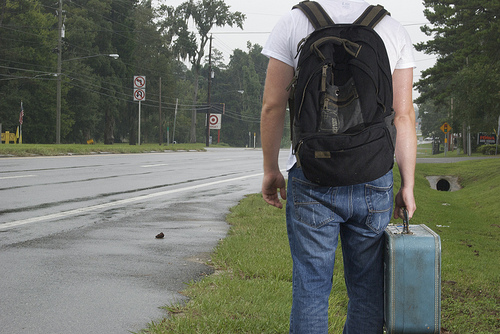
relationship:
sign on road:
[201, 107, 232, 146] [9, 131, 297, 309]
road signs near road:
[129, 73, 154, 150] [9, 131, 297, 309]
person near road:
[229, 0, 470, 333] [9, 131, 297, 309]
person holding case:
[229, 0, 470, 333] [372, 188, 448, 332]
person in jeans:
[229, 0, 470, 333] [258, 158, 412, 331]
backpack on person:
[278, 2, 404, 192] [229, 0, 470, 333]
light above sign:
[35, 6, 229, 151] [201, 107, 232, 146]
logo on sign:
[206, 114, 219, 125] [201, 107, 232, 146]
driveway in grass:
[371, 140, 498, 175] [260, 157, 500, 327]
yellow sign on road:
[437, 118, 460, 164] [9, 131, 297, 309]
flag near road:
[10, 93, 33, 147] [9, 131, 297, 309]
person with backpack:
[229, 0, 470, 333] [278, 2, 404, 192]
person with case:
[229, 0, 470, 333] [372, 188, 448, 332]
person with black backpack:
[229, 0, 470, 333] [278, 2, 404, 192]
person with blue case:
[229, 0, 470, 333] [372, 188, 448, 332]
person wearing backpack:
[229, 0, 470, 333] [278, 2, 404, 192]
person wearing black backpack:
[229, 0, 470, 333] [278, 2, 404, 192]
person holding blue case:
[229, 0, 470, 333] [372, 188, 448, 332]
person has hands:
[229, 0, 470, 333] [252, 171, 424, 221]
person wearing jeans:
[229, 0, 470, 333] [258, 158, 412, 331]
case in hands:
[372, 188, 448, 332] [252, 171, 424, 221]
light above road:
[35, 6, 229, 151] [9, 131, 297, 309]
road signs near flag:
[129, 73, 154, 150] [10, 93, 33, 147]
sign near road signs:
[201, 107, 232, 146] [129, 73, 154, 150]